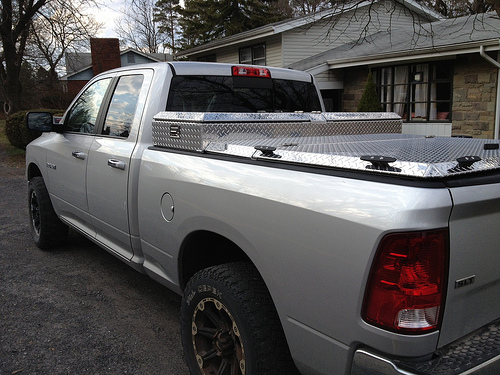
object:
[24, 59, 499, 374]
pickup truck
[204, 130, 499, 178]
cover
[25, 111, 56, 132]
sideview mirror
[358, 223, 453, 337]
brakelight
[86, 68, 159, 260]
door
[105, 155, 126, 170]
handle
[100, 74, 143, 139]
window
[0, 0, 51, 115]
tree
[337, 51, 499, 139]
wall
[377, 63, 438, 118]
curtain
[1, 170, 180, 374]
driveway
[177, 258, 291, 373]
tire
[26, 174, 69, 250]
tire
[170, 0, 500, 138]
house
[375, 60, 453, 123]
window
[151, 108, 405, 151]
tool box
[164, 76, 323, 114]
back window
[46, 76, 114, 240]
door